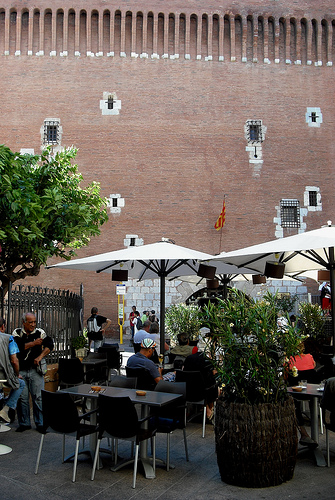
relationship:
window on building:
[39, 119, 69, 148] [2, 1, 332, 351]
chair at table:
[90, 391, 160, 494] [58, 380, 194, 478]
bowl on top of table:
[129, 386, 152, 402] [58, 380, 194, 478]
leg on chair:
[125, 440, 142, 489] [90, 391, 160, 494]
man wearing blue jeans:
[10, 309, 51, 434] [11, 369, 49, 431]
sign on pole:
[109, 282, 133, 298] [116, 292, 127, 347]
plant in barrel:
[168, 280, 323, 403] [206, 381, 301, 493]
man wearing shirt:
[10, 309, 51, 434] [10, 327, 52, 374]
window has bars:
[39, 119, 69, 148] [49, 128, 57, 138]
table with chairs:
[58, 380, 194, 478] [27, 385, 158, 491]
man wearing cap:
[129, 326, 169, 388] [130, 330, 159, 345]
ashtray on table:
[87, 384, 103, 397] [58, 380, 194, 478]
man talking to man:
[10, 309, 51, 434] [1, 317, 26, 427]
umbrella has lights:
[53, 234, 254, 292] [109, 262, 135, 285]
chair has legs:
[90, 391, 160, 494] [90, 434, 141, 491]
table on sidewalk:
[58, 380, 194, 478] [2, 407, 333, 499]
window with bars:
[39, 119, 69, 148] [49, 128, 57, 138]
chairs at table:
[27, 385, 158, 491] [58, 380, 194, 478]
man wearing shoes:
[10, 309, 51, 434] [14, 421, 48, 437]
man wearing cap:
[129, 326, 169, 388] [139, 338, 160, 351]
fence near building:
[1, 276, 93, 361] [2, 1, 332, 351]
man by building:
[10, 309, 51, 434] [2, 1, 332, 351]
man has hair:
[10, 309, 51, 434] [17, 310, 41, 333]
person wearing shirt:
[83, 306, 116, 342] [82, 314, 108, 341]